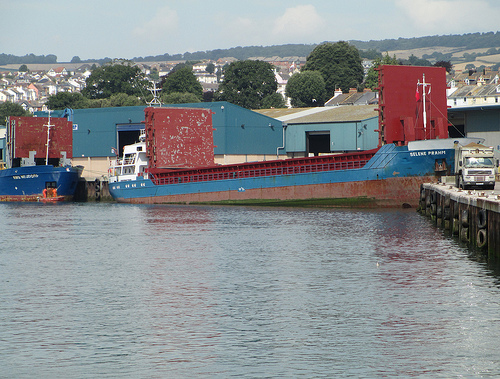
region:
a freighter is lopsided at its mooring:
[104, 61, 450, 221]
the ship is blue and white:
[102, 65, 442, 223]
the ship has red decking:
[141, 60, 451, 185]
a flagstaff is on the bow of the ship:
[411, 71, 442, 141]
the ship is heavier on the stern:
[86, 75, 175, 210]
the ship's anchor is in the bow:
[431, 153, 453, 180]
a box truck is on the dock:
[451, 139, 499, 188]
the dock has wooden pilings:
[416, 175, 498, 266]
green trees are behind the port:
[54, 43, 370, 109]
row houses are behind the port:
[0, 61, 499, 118]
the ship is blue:
[93, 106, 462, 192]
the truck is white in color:
[451, 144, 499, 190]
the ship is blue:
[3, 162, 79, 206]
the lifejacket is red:
[36, 183, 63, 203]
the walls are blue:
[220, 109, 274, 148]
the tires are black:
[421, 197, 485, 237]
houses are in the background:
[15, 58, 97, 94]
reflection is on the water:
[150, 225, 227, 310]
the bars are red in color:
[212, 156, 304, 175]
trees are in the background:
[197, 43, 314, 58]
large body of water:
[2, 195, 499, 377]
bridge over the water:
[413, 180, 498, 283]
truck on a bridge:
[450, 139, 497, 195]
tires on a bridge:
[416, 190, 491, 249]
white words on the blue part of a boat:
[406, 148, 448, 160]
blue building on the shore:
[6, 90, 388, 164]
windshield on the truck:
[463, 152, 497, 167]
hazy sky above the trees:
[1, 0, 498, 57]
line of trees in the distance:
[0, 24, 499, 66]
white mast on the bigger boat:
[414, 70, 435, 146]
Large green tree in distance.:
[309, 41, 384, 111]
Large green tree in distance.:
[290, 57, 337, 127]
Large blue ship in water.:
[174, 169, 398, 196]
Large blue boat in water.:
[3, 163, 88, 194]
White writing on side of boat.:
[7, 172, 34, 177]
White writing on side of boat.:
[399, 143, 461, 162]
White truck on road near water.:
[451, 139, 491, 185]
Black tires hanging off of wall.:
[434, 210, 491, 233]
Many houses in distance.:
[11, 67, 74, 97]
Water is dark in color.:
[44, 205, 300, 357]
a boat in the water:
[105, 123, 484, 207]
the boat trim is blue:
[101, 144, 466, 201]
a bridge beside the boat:
[422, 173, 497, 258]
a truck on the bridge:
[435, 139, 495, 194]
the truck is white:
[450, 137, 495, 186]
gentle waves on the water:
[1, 210, 436, 366]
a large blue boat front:
[0, 154, 82, 202]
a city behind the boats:
[2, 55, 497, 110]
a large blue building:
[22, 102, 295, 165]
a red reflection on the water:
[135, 188, 233, 346]